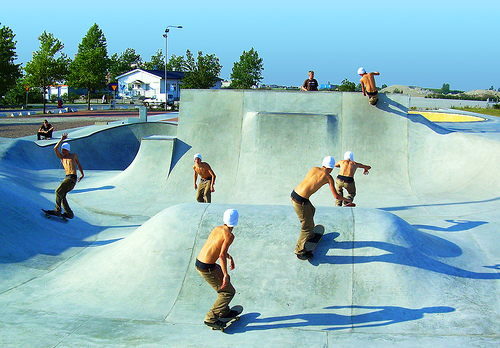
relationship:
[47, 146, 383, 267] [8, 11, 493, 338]
men skateboarding in park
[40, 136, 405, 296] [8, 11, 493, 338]
men skateboarding in park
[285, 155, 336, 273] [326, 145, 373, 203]
man skateboarding with man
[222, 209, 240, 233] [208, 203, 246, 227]
hat on head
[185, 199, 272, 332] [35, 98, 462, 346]
man skateboards course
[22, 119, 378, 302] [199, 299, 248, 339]
men are on skateboard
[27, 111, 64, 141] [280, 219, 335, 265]
person sits and watches skateboard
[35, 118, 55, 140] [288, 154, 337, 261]
person watches man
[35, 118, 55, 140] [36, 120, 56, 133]
person in shirt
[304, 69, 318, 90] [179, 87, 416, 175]
man at top of ramp